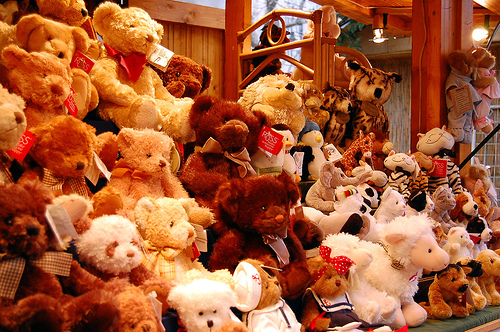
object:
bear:
[0, 170, 120, 332]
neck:
[0, 239, 45, 270]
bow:
[0, 251, 72, 299]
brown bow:
[111, 168, 148, 180]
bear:
[467, 46, 500, 134]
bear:
[92, 126, 217, 228]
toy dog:
[466, 216, 494, 258]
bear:
[300, 246, 391, 332]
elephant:
[305, 161, 373, 211]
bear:
[339, 59, 403, 147]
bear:
[89, 1, 197, 144]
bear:
[74, 210, 171, 315]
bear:
[17, 115, 105, 201]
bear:
[110, 282, 164, 331]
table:
[402, 304, 500, 332]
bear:
[209, 168, 325, 300]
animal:
[166, 279, 250, 332]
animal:
[180, 95, 270, 234]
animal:
[357, 212, 449, 329]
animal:
[0, 39, 73, 131]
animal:
[417, 125, 470, 197]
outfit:
[473, 67, 499, 130]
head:
[307, 256, 350, 300]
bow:
[319, 245, 357, 274]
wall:
[411, 0, 471, 156]